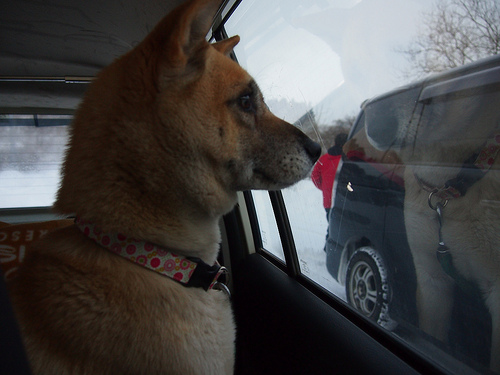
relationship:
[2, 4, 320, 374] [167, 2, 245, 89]
dog has ears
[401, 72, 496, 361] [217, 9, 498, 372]
reflection in window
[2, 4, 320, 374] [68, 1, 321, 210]
dog has head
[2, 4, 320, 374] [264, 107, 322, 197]
dog has nose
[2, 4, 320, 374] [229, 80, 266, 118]
dog has eye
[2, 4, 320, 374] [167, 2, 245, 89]
dog has ear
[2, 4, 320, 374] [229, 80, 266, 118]
dog with eye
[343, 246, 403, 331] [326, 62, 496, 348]
wheel on minivan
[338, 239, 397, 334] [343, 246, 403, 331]
snow covering wheel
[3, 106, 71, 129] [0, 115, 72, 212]
antenna on windshield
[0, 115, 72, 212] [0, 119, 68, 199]
windshield has defroster lines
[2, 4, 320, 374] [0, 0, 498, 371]
dog in car